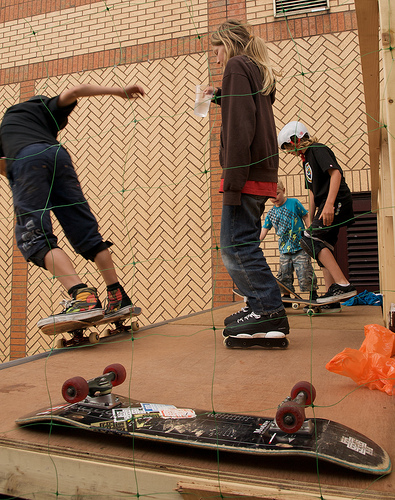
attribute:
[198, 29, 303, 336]
girl — blonde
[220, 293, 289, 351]
skates — black, white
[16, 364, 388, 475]
skateboard — upside-down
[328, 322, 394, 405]
paper — orange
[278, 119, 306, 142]
helmet — white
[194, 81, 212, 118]
glass — clear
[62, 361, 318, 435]
wheels — red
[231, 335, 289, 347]
wheels — white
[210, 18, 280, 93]
ponytail — blonde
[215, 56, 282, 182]
jacket — brown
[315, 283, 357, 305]
sneakers — black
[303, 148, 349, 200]
shirt — black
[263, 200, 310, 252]
shirt — blue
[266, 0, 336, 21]
vent — white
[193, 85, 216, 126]
cup — plastic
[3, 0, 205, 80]
wall — brick